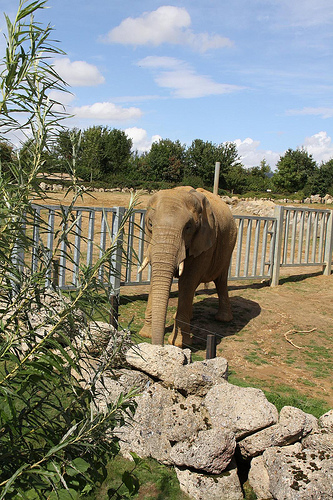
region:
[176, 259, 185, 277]
the left tusk of an elephant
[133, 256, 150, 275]
the right tusk of an elephant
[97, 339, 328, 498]
a group of small boulders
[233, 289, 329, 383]
the brown dirt covered ground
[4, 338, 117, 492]
the leaves from a bush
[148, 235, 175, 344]
the trunk of an elephant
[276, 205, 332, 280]
a white fence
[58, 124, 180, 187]
large green bushes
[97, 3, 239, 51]
a white puffy cloud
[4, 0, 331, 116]
the blue cloudy sky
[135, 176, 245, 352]
The elephant is brown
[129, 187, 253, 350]
The elephant is young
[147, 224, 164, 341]
Elephant has a wrinkled trunk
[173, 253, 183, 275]
Elephant has a small tusk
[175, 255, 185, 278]
Elephant's tusk is white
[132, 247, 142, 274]
Elephant has a small tusk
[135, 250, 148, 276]
Elephant's tusk is white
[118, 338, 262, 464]
Big rocks for elephant enclosure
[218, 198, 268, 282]
Metal fence is gray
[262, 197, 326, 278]
Fence has a gray gate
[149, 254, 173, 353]
an elephant trunk reaching over a wire fence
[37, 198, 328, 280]
a metal fence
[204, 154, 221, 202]
a round floor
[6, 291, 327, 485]
a stone wall behind a fence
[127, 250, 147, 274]
the tusk of an elephant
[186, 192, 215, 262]
an ear on an elephant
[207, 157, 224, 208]
a post in an enclosure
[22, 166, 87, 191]
a house in an enclosure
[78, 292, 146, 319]
grass in an elephant enclosure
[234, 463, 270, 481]
the rocks are big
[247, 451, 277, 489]
the rocks are big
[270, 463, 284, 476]
the rocks are big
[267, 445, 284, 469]
the rocks are big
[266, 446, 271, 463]
the rocks are big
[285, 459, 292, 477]
the rocks are big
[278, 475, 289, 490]
the rocks are big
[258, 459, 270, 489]
the rocks are big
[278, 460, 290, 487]
the rocks are big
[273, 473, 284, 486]
the rocks are big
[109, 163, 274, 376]
the elephant is brown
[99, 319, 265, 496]
the rocks are gray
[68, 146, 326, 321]
the fence is gray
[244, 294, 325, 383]
grass on the ground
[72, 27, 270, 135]
the sky has clouds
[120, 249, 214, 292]
the tusks are white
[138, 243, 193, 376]
the trunk is long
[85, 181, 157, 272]
the ground is made of soil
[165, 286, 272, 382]
shadow on the ground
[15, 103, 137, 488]
the leaves are green